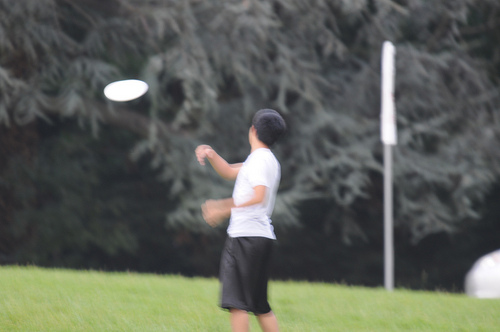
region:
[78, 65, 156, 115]
White frisbee in the air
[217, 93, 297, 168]
A boy with black hair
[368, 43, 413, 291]
A metal post with a white sign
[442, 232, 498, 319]
A white rock on the grass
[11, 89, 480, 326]
The boy is standing on the grass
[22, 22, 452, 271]
Dense dark green foliage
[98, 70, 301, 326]
The boy threw a frisbee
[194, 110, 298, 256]
The boy has a white shirt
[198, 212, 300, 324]
The boy has black shorts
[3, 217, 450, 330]
The trees surround the grass field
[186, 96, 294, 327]
a man in black shorts and a white shirt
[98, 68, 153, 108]
a white frisbee in the air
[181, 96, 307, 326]
a man who just threw a frisbee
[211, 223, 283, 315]
a pair of black basketball shorts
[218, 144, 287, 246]
a plain white t shirt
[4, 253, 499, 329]
a patch of green grass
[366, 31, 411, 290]
a white post in the background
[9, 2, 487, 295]
dark green trees in the background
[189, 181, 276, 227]
a blurry left arm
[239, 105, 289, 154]
the back of a man's head with short black hair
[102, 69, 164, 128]
White frisbee in the air.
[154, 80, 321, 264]
Man is throwing frisbee.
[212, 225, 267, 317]
Man wearing black shorts.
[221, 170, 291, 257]
Man wearing white shirt.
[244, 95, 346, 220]
Man has black hair.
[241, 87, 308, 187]
Man has short hair.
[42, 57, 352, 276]
Man is playing frisbee.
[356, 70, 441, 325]
Tall pole sticking out of the ground.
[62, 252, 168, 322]
Grass is green.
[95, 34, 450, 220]
Large trees in background.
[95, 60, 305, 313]
One man is playing Frisbee.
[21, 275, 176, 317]
Grass is green color.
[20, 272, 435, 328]
Man is standing in grass.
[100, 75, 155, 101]
Frisbee is white color.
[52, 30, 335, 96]
Trees are green color.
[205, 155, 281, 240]
Man is wearing white shirt.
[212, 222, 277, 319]
Man is wearing black shorts.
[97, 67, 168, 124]
Frisbee is flying in air.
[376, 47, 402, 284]
One pole is standing in grass.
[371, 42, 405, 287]
Pole is grey color.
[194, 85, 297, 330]
Boy in black shorts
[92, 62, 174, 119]
white frisbee flying in air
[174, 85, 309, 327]
boy in a white t-shirt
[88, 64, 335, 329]
boy playing with frisbee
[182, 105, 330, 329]
boy with black hair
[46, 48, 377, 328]
boy throwing frisbee in a park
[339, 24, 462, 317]
white sign in a park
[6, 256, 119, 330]
green grass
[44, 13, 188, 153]
frisbee flying through the air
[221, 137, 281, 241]
short sleeved white t-shirt